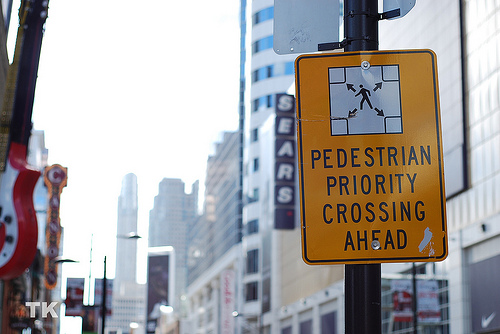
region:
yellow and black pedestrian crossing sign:
[269, 35, 463, 283]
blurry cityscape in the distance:
[115, 162, 266, 273]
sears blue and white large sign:
[274, 77, 308, 242]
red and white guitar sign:
[18, 16, 60, 264]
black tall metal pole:
[326, 274, 381, 331]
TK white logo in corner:
[26, 293, 87, 330]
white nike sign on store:
[466, 295, 498, 322]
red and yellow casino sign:
[50, 165, 61, 288]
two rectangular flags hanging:
[64, 252, 129, 327]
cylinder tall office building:
[226, 36, 294, 304]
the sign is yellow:
[297, 60, 451, 271]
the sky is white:
[81, 85, 197, 144]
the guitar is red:
[3, 102, 49, 281]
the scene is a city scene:
[7, 2, 497, 314]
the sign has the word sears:
[275, 93, 312, 223]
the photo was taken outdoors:
[5, 99, 498, 329]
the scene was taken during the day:
[3, 18, 459, 331]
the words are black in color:
[324, 145, 425, 250]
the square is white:
[325, 64, 390, 134]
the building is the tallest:
[110, 160, 145, 285]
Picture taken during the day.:
[43, 39, 458, 271]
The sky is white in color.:
[69, 18, 198, 156]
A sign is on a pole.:
[315, 98, 457, 285]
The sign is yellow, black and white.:
[292, 98, 451, 275]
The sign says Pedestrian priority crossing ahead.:
[290, 70, 450, 300]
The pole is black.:
[347, 278, 377, 318]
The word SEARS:
[265, 93, 297, 238]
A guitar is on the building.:
[11, 12, 54, 253]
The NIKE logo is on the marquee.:
[473, 232, 499, 326]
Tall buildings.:
[111, 117, 225, 317]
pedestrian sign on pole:
[289, 48, 457, 283]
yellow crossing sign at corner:
[289, 46, 446, 271]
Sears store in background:
[261, 41, 464, 329]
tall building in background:
[225, 8, 275, 332]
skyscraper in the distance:
[99, 167, 146, 330]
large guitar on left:
[3, 6, 61, 304]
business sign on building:
[41, 159, 71, 311]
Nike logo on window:
[471, 308, 498, 328]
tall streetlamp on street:
[78, 220, 138, 317]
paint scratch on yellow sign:
[404, 216, 447, 262]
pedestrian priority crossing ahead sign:
[290, 60, 478, 277]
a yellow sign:
[269, 46, 458, 301]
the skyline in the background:
[76, 44, 231, 312]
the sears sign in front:
[263, 89, 307, 249]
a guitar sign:
[0, 16, 49, 284]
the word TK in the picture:
[30, 294, 71, 319]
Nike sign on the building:
[460, 296, 498, 329]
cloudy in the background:
[66, 23, 221, 125]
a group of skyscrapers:
[75, 170, 265, 285]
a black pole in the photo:
[89, 248, 126, 332]